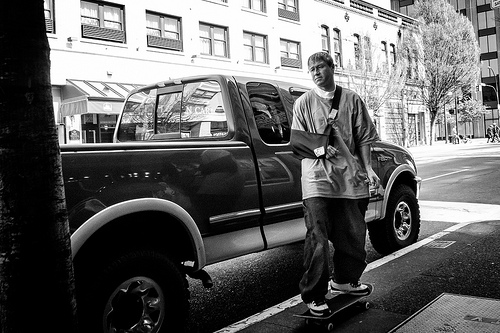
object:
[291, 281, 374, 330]
skateboard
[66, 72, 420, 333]
truck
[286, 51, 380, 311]
boy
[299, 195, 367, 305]
jeans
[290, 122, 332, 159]
sling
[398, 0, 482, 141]
tree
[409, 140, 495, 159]
sidewalk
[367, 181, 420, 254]
tire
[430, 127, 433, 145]
trunk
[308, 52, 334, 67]
hair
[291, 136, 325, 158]
arm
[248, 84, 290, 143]
window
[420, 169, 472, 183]
line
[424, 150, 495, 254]
street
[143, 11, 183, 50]
window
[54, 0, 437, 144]
building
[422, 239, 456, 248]
curb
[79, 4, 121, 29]
curtains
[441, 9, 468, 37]
leaves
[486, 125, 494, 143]
people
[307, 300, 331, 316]
shoes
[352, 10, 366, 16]
glasses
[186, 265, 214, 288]
pipe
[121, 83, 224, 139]
rear windshield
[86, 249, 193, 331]
rear tire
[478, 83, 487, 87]
lights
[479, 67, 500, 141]
lamp post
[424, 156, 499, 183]
two lanes